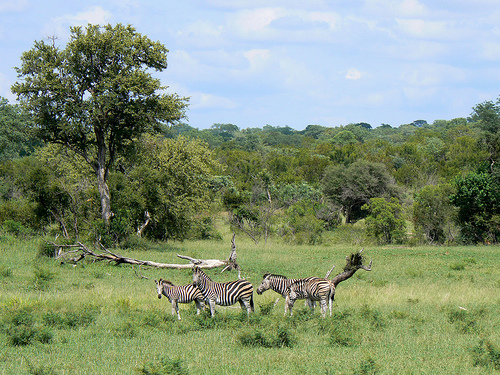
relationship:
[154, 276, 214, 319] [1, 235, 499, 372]
zebra in a field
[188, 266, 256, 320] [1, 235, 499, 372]
zebra in a field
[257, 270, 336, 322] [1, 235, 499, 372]
zebra in a field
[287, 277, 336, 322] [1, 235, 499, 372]
zebra in a field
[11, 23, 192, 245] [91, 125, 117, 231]
tree has trunk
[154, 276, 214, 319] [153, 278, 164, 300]
zebra has head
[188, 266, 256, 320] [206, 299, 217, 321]
zebra has leg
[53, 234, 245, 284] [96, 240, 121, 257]
tree has branch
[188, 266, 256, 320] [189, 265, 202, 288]
zebra has head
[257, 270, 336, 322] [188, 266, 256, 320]
zebra looking at zebra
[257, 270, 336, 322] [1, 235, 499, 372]
zebra in field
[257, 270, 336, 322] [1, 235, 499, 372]
zebra on field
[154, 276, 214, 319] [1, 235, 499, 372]
zebra in field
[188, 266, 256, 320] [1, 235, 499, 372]
zebra in field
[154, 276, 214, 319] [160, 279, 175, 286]
zebra has mane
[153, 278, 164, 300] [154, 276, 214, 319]
head on zebra